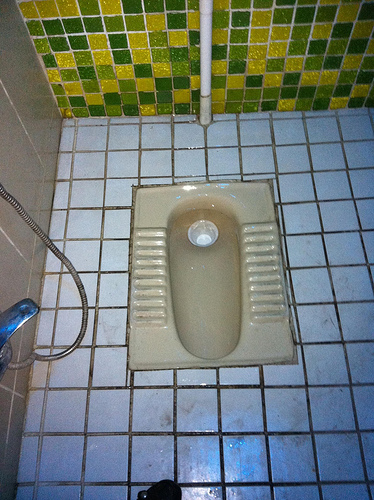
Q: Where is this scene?
A: Bathroom.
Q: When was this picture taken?
A: Before using bathroom.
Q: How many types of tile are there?
A: Three.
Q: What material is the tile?
A: Porcelain.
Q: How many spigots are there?
A: One.